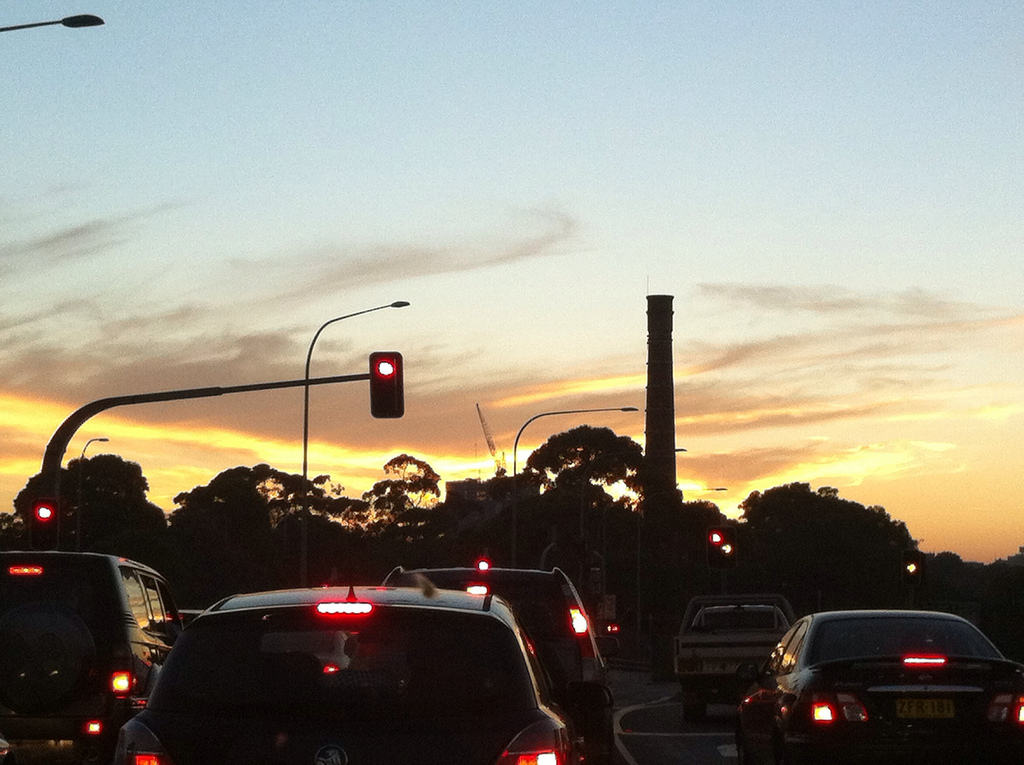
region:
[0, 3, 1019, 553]
clouds under blue sky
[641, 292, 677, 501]
silhouette of smoke stack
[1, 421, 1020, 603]
silhouette of tree tops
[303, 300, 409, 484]
street light on curved pole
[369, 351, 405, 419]
glowing round traffic light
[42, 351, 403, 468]
traffic light on horizontal pole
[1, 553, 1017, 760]
rear view of vehicles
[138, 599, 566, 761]
glowing brake lights on vehicle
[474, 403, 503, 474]
top of industrial crane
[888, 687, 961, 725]
license plate on car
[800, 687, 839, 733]
left brake light on car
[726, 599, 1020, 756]
black car on the street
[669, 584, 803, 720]
truck on the road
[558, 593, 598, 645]
right brake light on truck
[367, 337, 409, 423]
red traffic light hanging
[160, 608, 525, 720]
back window on truck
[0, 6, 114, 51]
light post in air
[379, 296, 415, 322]
light hanging in air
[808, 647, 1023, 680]
spoiler on back of car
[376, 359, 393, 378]
bright light is red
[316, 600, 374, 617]
bright light is red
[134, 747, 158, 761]
bright light is red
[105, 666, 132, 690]
bright light is red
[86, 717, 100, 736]
bright light is red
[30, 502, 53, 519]
bright light is red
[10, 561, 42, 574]
bright light is red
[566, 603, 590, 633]
bright light is red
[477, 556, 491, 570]
bright light is red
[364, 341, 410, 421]
traffic signal over the road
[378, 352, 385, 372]
red light on the traffic signal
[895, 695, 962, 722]
yellow license plat eon the car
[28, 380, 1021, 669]
trees in front of the traffic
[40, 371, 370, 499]
pole the traffic signal is attached to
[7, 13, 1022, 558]
blue sky fading to yellow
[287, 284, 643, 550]
street lights in front of the trees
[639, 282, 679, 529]
tower in front of the trees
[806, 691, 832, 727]
Brake light on the car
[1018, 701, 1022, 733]
Brake light on the car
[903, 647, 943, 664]
Brake light on the car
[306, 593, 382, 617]
Brake light on the car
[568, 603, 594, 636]
Brake light on the car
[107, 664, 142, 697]
Brake light on the car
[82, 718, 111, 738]
Brake light on the car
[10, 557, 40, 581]
Brake light on the car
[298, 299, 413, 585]
A tall light pole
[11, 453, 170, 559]
A tree in the distance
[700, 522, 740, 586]
A traffic signal ahead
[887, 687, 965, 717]
license plate on the black car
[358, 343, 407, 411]
traffic signal above the road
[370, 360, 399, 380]
light on the traffic signal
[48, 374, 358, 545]
pole traffic signal is attached to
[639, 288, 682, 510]
tower behind the trees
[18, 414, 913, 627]
trees in front of the cars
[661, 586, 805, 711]
white truck on the road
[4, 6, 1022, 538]
blue sky fading to yellow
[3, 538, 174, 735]
black suv on the road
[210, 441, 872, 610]
the trees are in the distance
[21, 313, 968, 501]
the clouds are in the sky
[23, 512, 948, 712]
the cars are on the road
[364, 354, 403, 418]
the light is signaling red